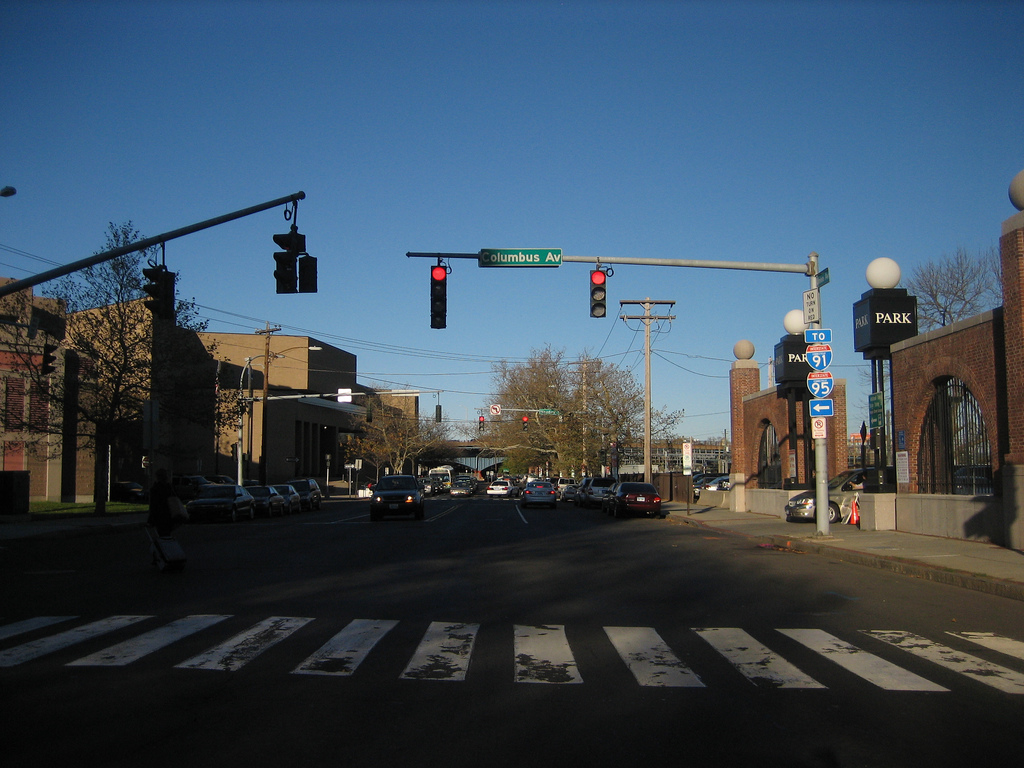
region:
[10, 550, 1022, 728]
lines of the cross walk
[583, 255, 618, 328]
the red stop light with only three lights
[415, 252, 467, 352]
The stop light with four lights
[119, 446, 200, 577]
The person walking on the road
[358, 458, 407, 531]
The car riving toward the camera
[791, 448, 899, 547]
The car coming out of the parking lost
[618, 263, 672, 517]
The electrical pol on the right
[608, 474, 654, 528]
The red parked car on the street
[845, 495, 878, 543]
The traffic cone at the entrance of the parking lot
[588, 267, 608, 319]
an electric traffic signal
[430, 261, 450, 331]
an electric traffic signal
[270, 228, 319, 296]
back of an electric traffic signal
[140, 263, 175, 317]
back of an an electric traffic signal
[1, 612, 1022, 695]
a white marked pedestrian crosswalk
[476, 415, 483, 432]
an electric traffic signal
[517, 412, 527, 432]
an electric traffic signal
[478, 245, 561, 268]
a green street name sign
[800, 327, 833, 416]
highway directional signs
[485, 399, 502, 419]
a no left turn sign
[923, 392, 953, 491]
glass is clean and clear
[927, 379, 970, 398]
glass is clean and clear